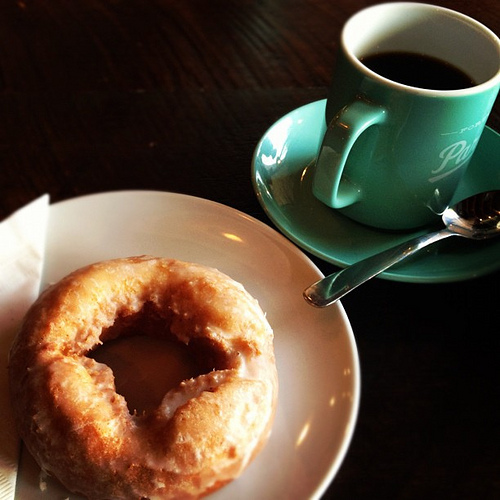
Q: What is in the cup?
A: Coffee.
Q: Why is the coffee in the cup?
A: To drink.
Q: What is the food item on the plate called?
A: Doughnut.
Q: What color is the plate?
A: White.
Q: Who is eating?
A: No one.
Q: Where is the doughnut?
A: On the plate.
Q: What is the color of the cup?
A: Green.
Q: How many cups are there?
A: One.